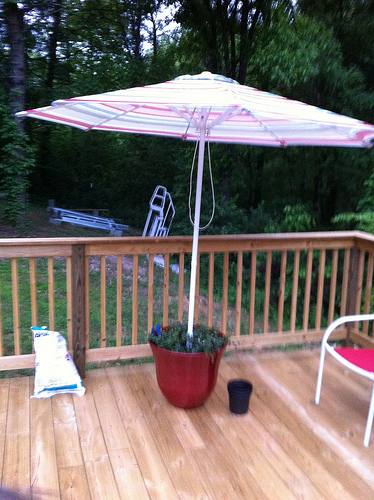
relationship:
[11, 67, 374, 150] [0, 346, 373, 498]
umbrella on deck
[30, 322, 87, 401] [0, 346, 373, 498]
bag on deck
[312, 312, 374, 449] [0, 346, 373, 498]
chair on deck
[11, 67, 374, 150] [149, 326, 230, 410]
umbrella in planter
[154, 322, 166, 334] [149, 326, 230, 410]
flower in planter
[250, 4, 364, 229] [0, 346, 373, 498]
tree behind deck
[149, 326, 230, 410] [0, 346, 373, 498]
planter on deck